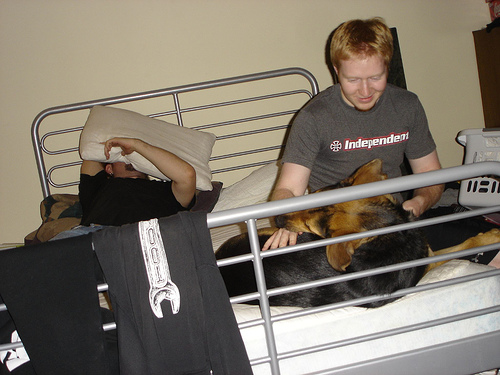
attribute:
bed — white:
[229, 179, 294, 292]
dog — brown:
[337, 187, 388, 256]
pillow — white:
[84, 111, 187, 144]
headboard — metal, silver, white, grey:
[208, 87, 255, 128]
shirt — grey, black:
[329, 97, 389, 156]